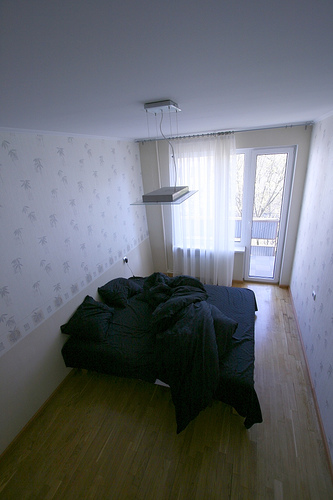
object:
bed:
[60, 271, 263, 434]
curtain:
[168, 131, 236, 288]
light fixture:
[130, 98, 199, 206]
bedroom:
[0, 0, 332, 499]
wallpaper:
[0, 128, 151, 358]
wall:
[0, 126, 155, 462]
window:
[169, 148, 248, 247]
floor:
[1, 272, 333, 499]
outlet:
[122, 255, 129, 264]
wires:
[159, 108, 177, 187]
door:
[243, 147, 295, 284]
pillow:
[60, 294, 116, 343]